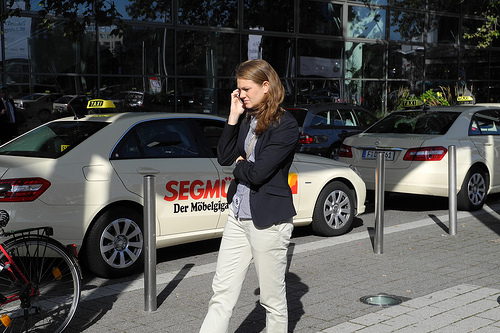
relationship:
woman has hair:
[195, 53, 298, 332] [235, 55, 287, 136]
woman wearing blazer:
[195, 59, 297, 333] [217, 109, 298, 230]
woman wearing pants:
[195, 59, 297, 333] [185, 193, 312, 331]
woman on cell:
[195, 53, 298, 332] [235, 90, 246, 106]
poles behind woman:
[447, 145, 458, 236] [224, 54, 299, 327]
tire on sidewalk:
[0, 233, 83, 332] [8, 192, 499, 327]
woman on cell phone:
[195, 53, 298, 332] [235, 89, 245, 102]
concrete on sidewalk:
[73, 202, 498, 329] [3, 200, 484, 330]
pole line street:
[372, 153, 386, 254] [0, 114, 484, 307]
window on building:
[31, 12, 98, 77] [0, 1, 483, 116]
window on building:
[95, 20, 146, 76] [0, 1, 483, 116]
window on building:
[382, 37, 427, 80] [0, 1, 483, 116]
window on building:
[288, 33, 344, 78] [0, 1, 483, 116]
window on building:
[166, 27, 208, 83] [0, 1, 483, 116]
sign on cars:
[455, 93, 472, 105] [337, 96, 500, 212]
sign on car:
[87, 101, 112, 114] [2, 99, 367, 278]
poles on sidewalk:
[127, 140, 462, 314] [3, 200, 484, 330]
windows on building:
[3, 3, 498, 135] [0, 1, 483, 116]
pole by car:
[143, 172, 158, 310] [2, 111, 367, 278]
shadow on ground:
[233, 272, 308, 331] [0, 196, 499, 331]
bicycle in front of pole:
[0, 209, 85, 332] [139, 171, 160, 313]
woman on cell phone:
[195, 53, 298, 332] [236, 90, 244, 107]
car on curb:
[2, 111, 367, 278] [0, 200, 498, 319]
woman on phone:
[195, 53, 298, 332] [235, 88, 241, 101]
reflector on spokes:
[50, 267, 60, 279] [2, 242, 73, 328]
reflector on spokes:
[2, 316, 12, 326] [2, 242, 73, 328]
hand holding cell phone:
[228, 87, 243, 127] [237, 93, 244, 104]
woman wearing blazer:
[195, 59, 297, 333] [220, 101, 305, 226]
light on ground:
[361, 288, 403, 311] [248, 232, 466, 321]